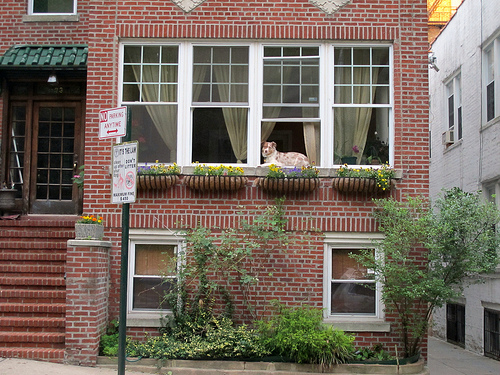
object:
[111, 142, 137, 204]
sign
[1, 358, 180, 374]
street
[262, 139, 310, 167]
dog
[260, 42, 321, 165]
window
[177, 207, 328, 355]
bushes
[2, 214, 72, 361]
stairs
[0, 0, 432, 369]
building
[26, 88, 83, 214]
door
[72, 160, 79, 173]
handle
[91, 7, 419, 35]
brick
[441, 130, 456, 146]
air conditioner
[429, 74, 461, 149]
window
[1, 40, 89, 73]
overhang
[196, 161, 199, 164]
flowers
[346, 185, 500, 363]
tree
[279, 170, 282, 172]
flowers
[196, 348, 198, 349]
flowers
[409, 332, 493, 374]
alley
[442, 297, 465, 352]
door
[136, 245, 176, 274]
board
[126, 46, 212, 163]
curtains